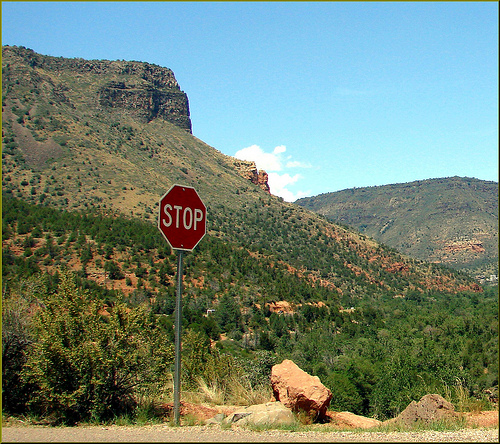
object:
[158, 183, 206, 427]
stop sign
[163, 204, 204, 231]
stop letters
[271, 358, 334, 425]
rock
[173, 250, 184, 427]
pole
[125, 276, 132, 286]
trees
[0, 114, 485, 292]
mountainside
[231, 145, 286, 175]
clouds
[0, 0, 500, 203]
sky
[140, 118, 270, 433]
mountain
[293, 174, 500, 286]
mountain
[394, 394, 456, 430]
rock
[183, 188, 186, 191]
bolt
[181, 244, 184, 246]
bolt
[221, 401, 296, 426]
rock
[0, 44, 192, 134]
mountaintop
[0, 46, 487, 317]
earth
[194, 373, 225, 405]
weeds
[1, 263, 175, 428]
bush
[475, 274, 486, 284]
buildings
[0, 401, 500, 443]
road shoulder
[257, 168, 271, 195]
boulder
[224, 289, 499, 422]
prairie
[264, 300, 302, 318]
patch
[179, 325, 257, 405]
bushes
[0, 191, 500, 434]
foot of hill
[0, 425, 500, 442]
path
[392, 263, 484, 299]
valley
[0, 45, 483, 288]
vegetation